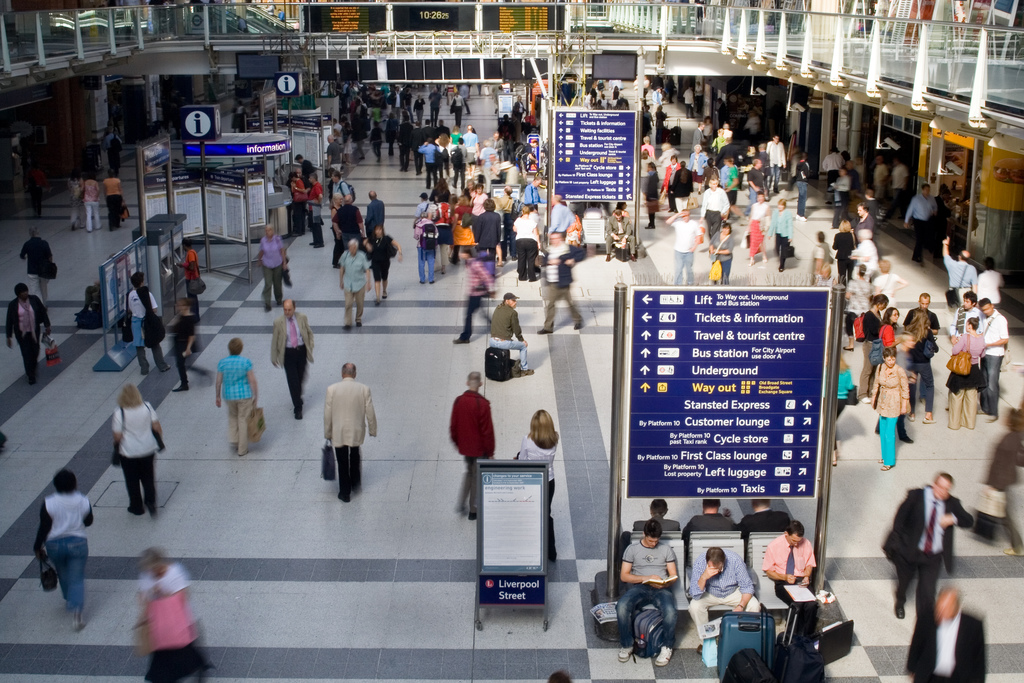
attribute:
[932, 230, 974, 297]
man — balding, blue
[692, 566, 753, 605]
shirt — blue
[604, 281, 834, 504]
sign — blue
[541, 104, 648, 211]
sign — blue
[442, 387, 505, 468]
jacket — red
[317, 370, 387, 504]
suit — gray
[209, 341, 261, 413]
shirt — blue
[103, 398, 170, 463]
shirt — white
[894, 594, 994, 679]
suit — black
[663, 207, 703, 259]
shirt — white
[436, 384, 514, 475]
coat — red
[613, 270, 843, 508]
sign — blue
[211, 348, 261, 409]
top — blue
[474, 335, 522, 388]
bag — black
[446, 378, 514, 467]
jacket — red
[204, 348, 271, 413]
shirt — blue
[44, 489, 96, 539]
shirt — white 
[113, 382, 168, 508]
woman — blond 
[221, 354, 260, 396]
shirt — blue 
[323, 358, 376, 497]
man — bald 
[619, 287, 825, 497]
sign — Blue 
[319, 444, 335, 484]
briefcase — brown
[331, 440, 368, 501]
pant — black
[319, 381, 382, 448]
jacket — tan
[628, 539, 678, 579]
shirt — gray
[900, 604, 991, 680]
jacket — black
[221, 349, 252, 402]
shirt — blue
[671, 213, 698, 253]
shirt — white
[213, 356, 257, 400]
shirt — blue 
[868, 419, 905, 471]
pants — aqua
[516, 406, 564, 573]
person — standing up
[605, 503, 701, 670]
person — sitting down 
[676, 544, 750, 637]
person — sitting down 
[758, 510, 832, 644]
person — sitting down 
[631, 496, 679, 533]
person — sitting down 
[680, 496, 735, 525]
person — sitting down 